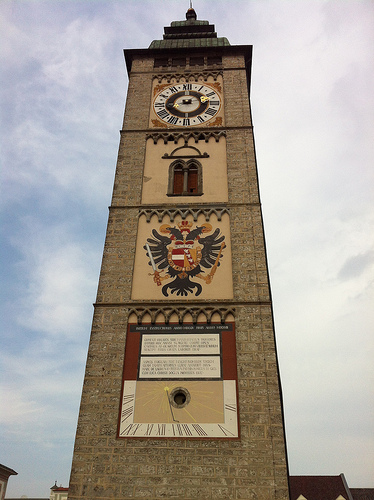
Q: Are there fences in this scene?
A: No, there are no fences.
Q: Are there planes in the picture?
A: No, there are no planes.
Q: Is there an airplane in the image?
A: No, there are no airplanes.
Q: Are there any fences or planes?
A: No, there are no planes or fences.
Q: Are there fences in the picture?
A: No, there are no fences.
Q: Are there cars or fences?
A: No, there are no fences or cars.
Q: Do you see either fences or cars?
A: No, there are no fences or cars.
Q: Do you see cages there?
A: No, there are no cages.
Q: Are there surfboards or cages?
A: No, there are no cages or surfboards.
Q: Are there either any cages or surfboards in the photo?
A: No, there are no cages or surfboards.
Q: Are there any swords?
A: Yes, there is a sword.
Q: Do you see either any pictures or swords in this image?
A: Yes, there is a sword.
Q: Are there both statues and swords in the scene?
A: No, there is a sword but no statues.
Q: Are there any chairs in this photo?
A: No, there are no chairs.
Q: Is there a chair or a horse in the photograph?
A: No, there are no chairs or horses.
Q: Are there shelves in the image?
A: No, there are no shelves.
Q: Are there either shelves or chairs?
A: No, there are no shelves or chairs.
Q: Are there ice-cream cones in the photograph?
A: No, there are no ice-cream cones.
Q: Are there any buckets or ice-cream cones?
A: No, there are no ice-cream cones or buckets.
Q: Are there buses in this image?
A: No, there are no buses.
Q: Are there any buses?
A: No, there are no buses.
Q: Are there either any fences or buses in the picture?
A: No, there are no buses or fences.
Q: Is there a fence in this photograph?
A: No, there are no fences.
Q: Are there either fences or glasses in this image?
A: No, there are no fences or glasses.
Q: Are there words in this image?
A: Yes, there are words.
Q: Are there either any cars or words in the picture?
A: Yes, there are words.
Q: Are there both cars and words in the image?
A: No, there are words but no cars.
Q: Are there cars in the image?
A: No, there are no cars.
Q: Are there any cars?
A: No, there are no cars.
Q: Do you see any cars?
A: No, there are no cars.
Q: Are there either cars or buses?
A: No, there are no cars or buses.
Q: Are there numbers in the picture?
A: Yes, there are numbers.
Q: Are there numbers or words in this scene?
A: Yes, there are numbers.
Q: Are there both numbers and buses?
A: No, there are numbers but no buses.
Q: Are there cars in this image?
A: No, there are no cars.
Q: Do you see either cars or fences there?
A: No, there are no cars or fences.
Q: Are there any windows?
A: Yes, there are windows.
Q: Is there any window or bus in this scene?
A: Yes, there are windows.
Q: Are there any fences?
A: No, there are no fences.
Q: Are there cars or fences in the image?
A: No, there are no fences or cars.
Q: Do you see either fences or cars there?
A: No, there are no fences or cars.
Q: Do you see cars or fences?
A: No, there are no fences or cars.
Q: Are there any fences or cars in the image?
A: No, there are no cars or fences.